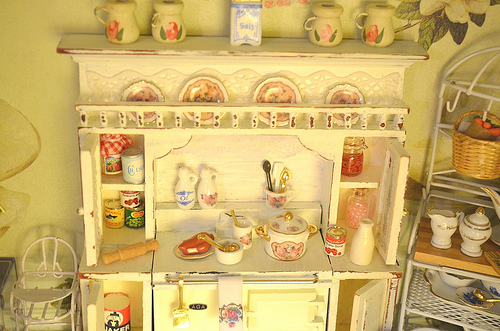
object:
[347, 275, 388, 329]
door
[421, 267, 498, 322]
platter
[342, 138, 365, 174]
jar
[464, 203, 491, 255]
jar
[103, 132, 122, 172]
jar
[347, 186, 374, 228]
jar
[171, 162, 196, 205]
jar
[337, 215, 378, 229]
shelf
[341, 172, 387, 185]
shelf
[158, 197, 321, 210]
shelf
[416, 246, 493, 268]
shelf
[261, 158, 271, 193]
spoon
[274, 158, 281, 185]
spoon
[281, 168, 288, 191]
spoon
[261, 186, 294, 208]
cup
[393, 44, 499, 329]
metal shelf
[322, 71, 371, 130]
plate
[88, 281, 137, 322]
box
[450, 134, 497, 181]
basket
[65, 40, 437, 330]
small wave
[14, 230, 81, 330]
chair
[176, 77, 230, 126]
plate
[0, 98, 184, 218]
wall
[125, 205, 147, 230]
can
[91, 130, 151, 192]
shelf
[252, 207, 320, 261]
pot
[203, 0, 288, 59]
container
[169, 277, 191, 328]
paint brush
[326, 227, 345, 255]
can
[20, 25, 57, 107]
wall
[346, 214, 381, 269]
vase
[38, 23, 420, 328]
table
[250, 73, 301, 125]
plate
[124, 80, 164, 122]
plate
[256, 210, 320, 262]
piece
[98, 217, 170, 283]
pen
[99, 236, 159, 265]
pin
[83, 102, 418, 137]
shelf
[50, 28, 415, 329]
dollhouse cupboard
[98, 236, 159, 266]
rolling pin